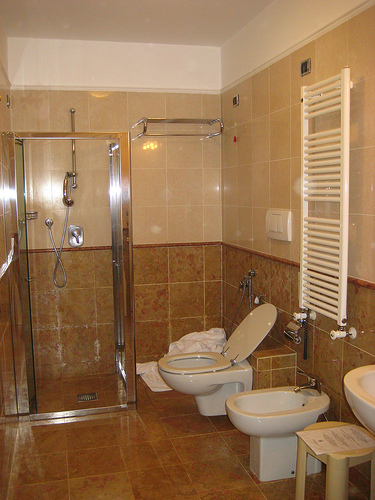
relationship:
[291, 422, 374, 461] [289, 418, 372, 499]
paper on stool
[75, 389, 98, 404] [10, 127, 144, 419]
drain in shower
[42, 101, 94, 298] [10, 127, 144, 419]
hose in shower stall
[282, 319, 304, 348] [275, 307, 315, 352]
toilet roll for dispenser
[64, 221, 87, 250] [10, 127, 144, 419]
valve for shower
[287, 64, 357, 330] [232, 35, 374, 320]
vents on wall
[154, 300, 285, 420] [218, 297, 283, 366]
toilet has a lid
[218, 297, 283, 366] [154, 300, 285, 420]
lid of a toilet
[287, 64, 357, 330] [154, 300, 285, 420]
window in front toilet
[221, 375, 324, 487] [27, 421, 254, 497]
sink on floor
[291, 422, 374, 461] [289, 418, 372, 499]
paper over stool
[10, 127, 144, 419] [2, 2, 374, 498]
shower in bathroom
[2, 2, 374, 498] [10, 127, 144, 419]
bathroom with shower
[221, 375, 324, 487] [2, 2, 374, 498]
bidet in bathroom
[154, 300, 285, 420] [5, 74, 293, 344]
toilet on wall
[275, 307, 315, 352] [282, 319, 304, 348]
holder for toilet paper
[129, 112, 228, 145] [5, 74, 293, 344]
rack on wall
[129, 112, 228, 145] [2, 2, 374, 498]
rack in bathroom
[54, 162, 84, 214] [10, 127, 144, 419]
hand sprayer in shower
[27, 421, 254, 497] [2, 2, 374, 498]
floor of bathroom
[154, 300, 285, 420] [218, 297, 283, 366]
toilet with lid up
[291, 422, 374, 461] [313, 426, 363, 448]
paper with black words